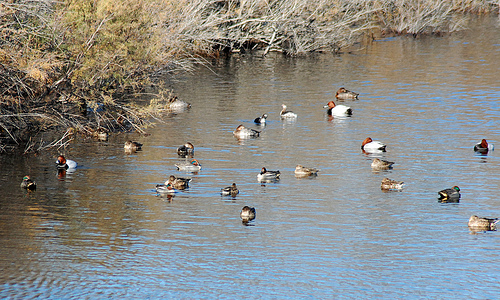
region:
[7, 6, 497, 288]
Ducks in the pond.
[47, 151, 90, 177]
Duck swimming in the water.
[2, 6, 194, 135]
Brush along the side of water.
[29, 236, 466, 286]
Water of a pond where ducks are.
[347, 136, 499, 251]
Six ducks in the water.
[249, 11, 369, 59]
Bare bush along side of water.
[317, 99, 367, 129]
Side view of white duck in water.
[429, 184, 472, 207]
Grey duck in the water.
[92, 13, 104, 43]
Twig branch of bushes.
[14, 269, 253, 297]
Ripples in the water.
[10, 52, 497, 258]
Ducks swimming in the water.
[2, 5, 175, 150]
Trees lining the bank.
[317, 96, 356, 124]
Duck with a brown head.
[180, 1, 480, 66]
Bare branches of the bushes on the bank.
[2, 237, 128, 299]
Ripples in the water.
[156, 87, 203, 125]
Duck swimming by the tree.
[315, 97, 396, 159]
White, black and brown ducks.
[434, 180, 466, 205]
Black duck with a green head.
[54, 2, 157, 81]
Green-yellow leaves on the tree.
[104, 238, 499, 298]
Blue sky reflecting off the water.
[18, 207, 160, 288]
this is the water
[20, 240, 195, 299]
there are ripples of water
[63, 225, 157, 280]
the water is still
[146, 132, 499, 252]
these are several ducks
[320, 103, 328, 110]
this is the duck's beak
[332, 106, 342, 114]
the feathers are white in color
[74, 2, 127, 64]
these are some leaves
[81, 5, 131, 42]
the leaves are green in color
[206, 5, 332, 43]
these are many branches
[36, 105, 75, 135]
the branches are leafless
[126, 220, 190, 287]
this is the water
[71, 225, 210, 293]
there are water ripples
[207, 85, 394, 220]
the ducks are on the water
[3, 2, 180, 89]
this is a bush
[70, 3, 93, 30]
the leaves are green in color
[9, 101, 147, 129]
these branches have no leaves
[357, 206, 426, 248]
part of a water body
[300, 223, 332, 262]
surface of some water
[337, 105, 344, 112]
white part of a duck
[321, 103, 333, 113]
beak of a duck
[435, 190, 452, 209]
tail feather of the duck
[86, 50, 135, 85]
part of some branches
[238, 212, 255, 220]
chest of a duck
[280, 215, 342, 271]
part of some waves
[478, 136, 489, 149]
red part of the duck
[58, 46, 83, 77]
part of a plant